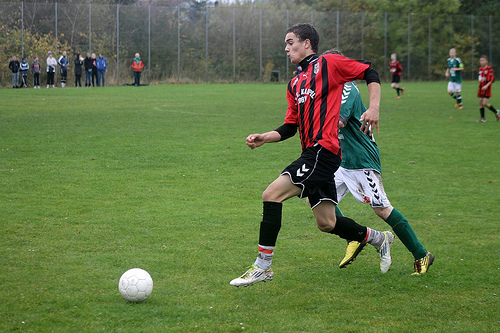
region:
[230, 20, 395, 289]
player in red and black uniform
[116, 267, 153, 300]
all white soccer ball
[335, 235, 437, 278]
yellow soccer cleats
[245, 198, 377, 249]
long black soccer socks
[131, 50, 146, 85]
person on sidelines wearing red and green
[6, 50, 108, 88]
spectators on the sidelines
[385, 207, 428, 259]
long green soccer sock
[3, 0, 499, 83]
tall fence behind field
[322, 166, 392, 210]
white soccer shorts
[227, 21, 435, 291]
players running for ball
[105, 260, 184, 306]
soccer ball on grass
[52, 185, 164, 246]
a portion of grass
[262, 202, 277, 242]
black sock on leg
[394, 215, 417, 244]
green sock on leg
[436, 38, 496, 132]
some of the soccer players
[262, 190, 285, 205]
one of the man's knees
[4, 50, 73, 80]
people on the sidelines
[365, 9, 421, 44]
leaves on the tree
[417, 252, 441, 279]
athletic shoe on foot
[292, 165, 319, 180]
design on black shorts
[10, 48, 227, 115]
the people are standing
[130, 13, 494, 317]
players are chasing the ball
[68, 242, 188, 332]
the ball on the ground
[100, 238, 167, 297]
the ball is white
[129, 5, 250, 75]
trees outside the fence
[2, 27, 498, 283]
people inside the fence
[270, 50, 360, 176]
the jersey is stripes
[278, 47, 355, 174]
the jersey is red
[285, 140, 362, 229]
the shorts are black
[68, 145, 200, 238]
grass on the ground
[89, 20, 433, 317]
two soccer players chasing a ball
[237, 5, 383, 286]
a player wearing a black and red jersey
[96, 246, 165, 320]
a white soccer ball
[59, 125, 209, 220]
lush green green on the field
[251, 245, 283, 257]
a red band on a sock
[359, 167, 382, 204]
black arrows on white shorts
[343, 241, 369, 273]
a yellow cleat on a foot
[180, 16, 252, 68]
a metal fence around the field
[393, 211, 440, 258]
green sock covering a leg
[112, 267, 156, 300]
a white soccer ball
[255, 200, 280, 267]
men's long socks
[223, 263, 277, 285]
white soccer shoes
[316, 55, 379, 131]
the arm of a boy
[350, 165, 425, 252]
the leg of a boy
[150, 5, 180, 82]
part of a fence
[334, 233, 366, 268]
yellow soccer cleats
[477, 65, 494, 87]
a short sleeve red jersey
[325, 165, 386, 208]
boy's white soccer shorts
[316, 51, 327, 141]
a long black stripe